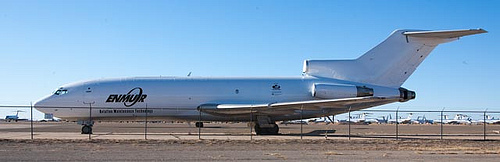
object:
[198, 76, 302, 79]
edge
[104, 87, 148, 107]
logo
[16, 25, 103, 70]
clouds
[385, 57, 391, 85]
ground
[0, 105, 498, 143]
fence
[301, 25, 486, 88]
white tail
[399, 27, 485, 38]
wing edge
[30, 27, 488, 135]
airplane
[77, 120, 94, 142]
landing gear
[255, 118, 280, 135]
landing gear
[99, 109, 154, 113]
letter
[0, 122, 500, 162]
tarmac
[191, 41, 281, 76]
clouds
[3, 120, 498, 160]
ground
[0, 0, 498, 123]
sky